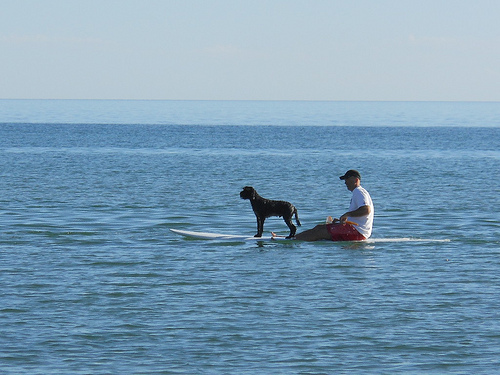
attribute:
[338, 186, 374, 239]
shirt — white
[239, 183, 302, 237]
dog — standing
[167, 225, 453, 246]
surfboard —  long, white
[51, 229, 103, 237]
ripple — small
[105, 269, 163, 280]
ripple — small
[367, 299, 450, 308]
ripple — small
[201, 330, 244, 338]
ripple — small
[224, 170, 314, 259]
dog — standing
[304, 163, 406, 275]
man — sitting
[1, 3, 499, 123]
sky — clear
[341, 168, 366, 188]
hat — black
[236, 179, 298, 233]
dog — black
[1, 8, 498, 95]
sky — clear , blue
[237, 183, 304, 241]
dog — black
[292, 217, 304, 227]
tail — black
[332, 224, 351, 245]
shorts — red